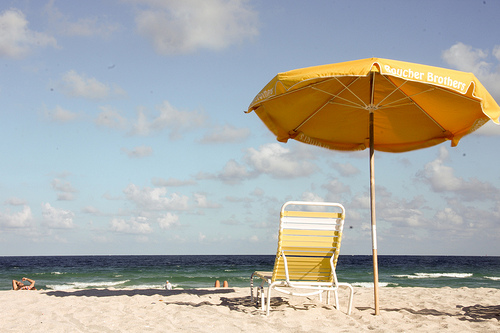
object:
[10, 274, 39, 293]
person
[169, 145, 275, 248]
sky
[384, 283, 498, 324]
beach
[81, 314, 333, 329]
beach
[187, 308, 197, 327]
sand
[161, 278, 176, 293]
someone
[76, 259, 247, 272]
ocean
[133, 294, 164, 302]
beach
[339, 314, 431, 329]
sand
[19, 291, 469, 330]
beach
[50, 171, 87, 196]
clouds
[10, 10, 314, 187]
sky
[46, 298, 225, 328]
sand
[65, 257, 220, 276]
water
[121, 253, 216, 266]
water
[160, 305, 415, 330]
beach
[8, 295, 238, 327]
beach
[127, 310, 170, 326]
sand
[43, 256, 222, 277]
water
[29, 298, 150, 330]
sand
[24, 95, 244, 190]
sky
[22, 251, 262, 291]
ocean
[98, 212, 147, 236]
clouds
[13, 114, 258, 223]
sky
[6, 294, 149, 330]
beach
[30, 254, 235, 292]
waves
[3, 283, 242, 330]
shore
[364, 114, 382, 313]
pole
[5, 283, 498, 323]
beach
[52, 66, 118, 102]
clouds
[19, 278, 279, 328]
sand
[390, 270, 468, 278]
caps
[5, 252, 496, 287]
water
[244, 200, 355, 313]
chair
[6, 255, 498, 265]
water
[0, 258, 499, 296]
ocean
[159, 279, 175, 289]
bird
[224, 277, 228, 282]
knees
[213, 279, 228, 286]
someone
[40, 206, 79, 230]
clouds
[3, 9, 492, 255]
sky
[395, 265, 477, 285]
waves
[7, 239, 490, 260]
horizon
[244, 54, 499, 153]
parasol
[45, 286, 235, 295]
shadows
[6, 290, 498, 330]
sand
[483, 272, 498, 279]
foam